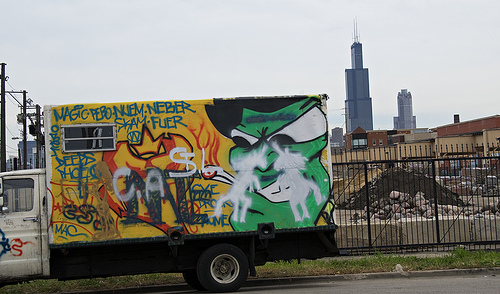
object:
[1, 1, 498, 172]
background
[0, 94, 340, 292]
truck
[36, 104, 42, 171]
pole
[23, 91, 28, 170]
pole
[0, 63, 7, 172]
pole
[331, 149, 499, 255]
fence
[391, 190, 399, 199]
rocks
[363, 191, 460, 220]
pile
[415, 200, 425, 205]
rocks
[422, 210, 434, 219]
rocks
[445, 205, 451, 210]
rocks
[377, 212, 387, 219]
rocks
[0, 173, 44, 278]
door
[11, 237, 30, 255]
graffiti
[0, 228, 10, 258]
graffiti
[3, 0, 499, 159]
sky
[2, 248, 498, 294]
grass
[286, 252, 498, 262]
sidewalk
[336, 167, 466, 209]
pile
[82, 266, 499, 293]
road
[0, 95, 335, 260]
paint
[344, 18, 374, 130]
building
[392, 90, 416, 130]
building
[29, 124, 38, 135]
power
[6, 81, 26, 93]
lines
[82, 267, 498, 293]
curb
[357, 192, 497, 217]
pile of rock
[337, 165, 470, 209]
pile of dirt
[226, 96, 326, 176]
face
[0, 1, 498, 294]
city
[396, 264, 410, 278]
trash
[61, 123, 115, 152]
window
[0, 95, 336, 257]
graffiti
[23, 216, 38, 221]
handle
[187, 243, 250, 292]
tire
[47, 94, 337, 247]
decoration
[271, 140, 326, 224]
unicorn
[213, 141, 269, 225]
unicorn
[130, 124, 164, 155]
crown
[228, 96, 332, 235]
caricature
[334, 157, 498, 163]
rail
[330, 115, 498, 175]
building